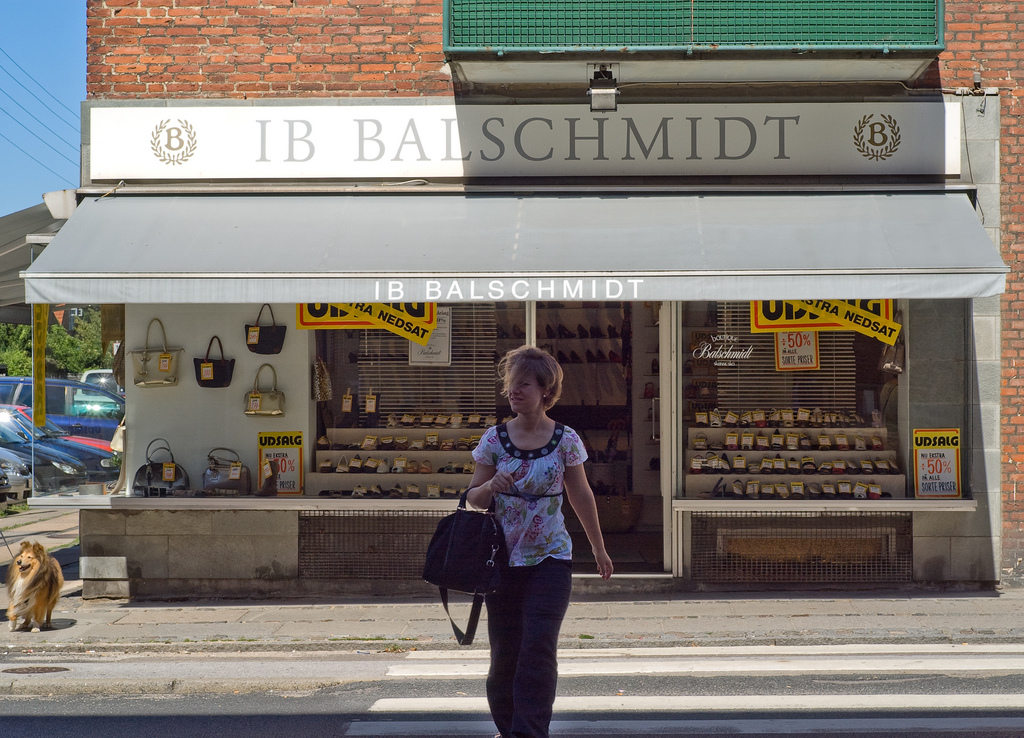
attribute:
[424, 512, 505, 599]
bag — black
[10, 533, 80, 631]
dog — brown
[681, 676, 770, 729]
lines — white